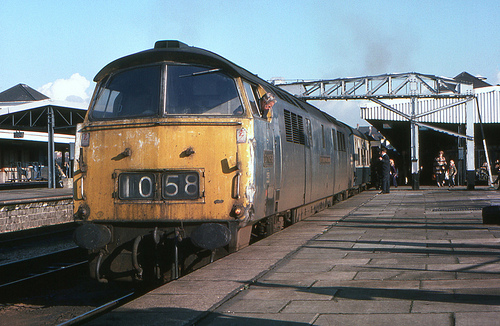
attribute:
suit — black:
[379, 152, 391, 193]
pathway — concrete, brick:
[200, 183, 498, 324]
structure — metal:
[265, 64, 496, 201]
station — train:
[5, 65, 495, 320]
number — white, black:
[118, 175, 134, 195]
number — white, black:
[133, 172, 155, 197]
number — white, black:
[159, 170, 180, 197]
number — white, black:
[183, 172, 198, 194]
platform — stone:
[118, 172, 495, 324]